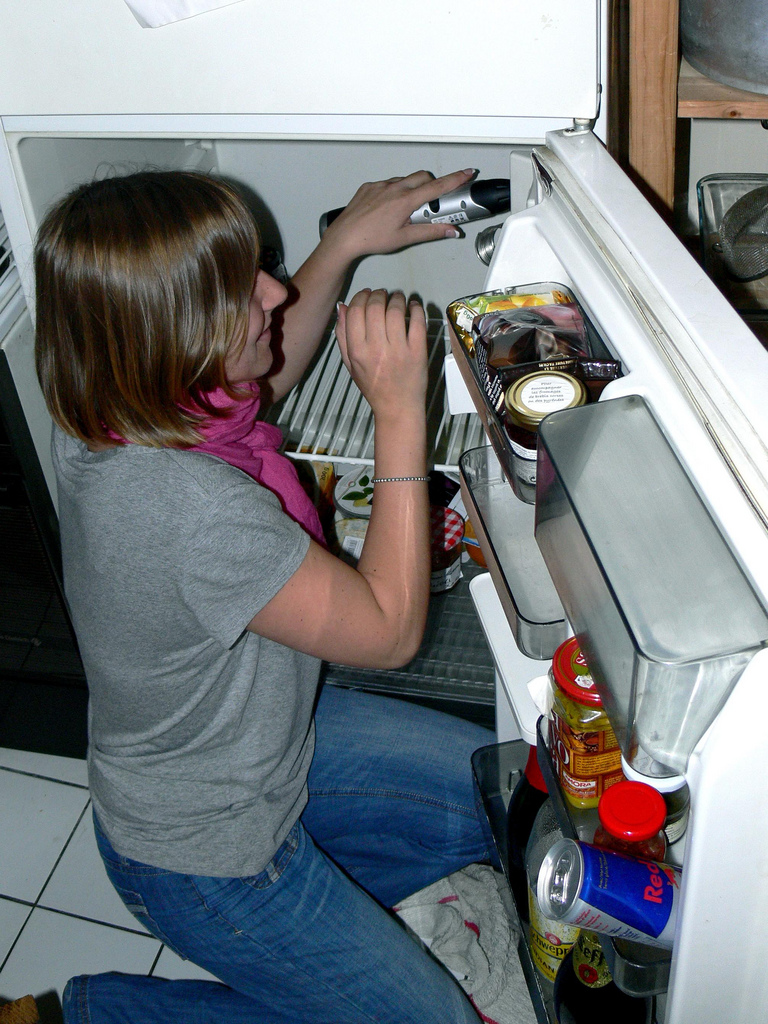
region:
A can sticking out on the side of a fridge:
[564, 863, 652, 909]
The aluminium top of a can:
[552, 850, 571, 905]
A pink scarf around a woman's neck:
[234, 425, 269, 465]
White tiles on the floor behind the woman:
[8, 803, 86, 895]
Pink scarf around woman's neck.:
[169, 395, 316, 526]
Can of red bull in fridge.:
[541, 838, 679, 921]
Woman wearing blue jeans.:
[93, 744, 469, 1021]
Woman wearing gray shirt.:
[36, 470, 316, 874]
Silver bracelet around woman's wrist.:
[366, 462, 431, 493]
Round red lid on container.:
[601, 778, 665, 856]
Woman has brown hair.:
[31, 231, 259, 449]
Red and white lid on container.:
[430, 506, 467, 558]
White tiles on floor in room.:
[6, 777, 146, 987]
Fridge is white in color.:
[12, 32, 740, 906]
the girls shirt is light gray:
[120, 496, 194, 610]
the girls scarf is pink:
[223, 412, 267, 456]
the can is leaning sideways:
[532, 838, 665, 929]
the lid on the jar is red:
[609, 786, 653, 824]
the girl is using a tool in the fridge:
[431, 172, 501, 225]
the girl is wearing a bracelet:
[381, 465, 417, 497]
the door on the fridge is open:
[480, 113, 756, 514]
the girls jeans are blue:
[282, 909, 375, 985]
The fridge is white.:
[576, 249, 704, 356]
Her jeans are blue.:
[243, 917, 351, 986]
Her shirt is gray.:
[98, 688, 207, 786]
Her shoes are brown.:
[2, 956, 60, 1006]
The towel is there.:
[443, 883, 490, 998]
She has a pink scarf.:
[204, 397, 323, 493]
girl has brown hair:
[97, 212, 297, 419]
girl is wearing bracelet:
[364, 464, 415, 496]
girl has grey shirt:
[97, 437, 313, 852]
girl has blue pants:
[160, 752, 536, 1022]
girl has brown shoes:
[6, 980, 56, 1018]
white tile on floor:
[12, 770, 67, 985]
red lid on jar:
[531, 650, 620, 801]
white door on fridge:
[496, 121, 766, 686]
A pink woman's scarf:
[75, 380, 337, 556]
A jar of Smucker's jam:
[410, 493, 469, 600]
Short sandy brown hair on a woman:
[28, 159, 273, 451]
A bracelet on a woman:
[359, 469, 435, 488]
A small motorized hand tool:
[315, 172, 530, 243]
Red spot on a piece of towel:
[456, 908, 487, 943]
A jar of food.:
[584, 791, 650, 854]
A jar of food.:
[627, 737, 687, 834]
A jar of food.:
[534, 631, 648, 781]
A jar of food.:
[496, 368, 604, 472]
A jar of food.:
[430, 498, 483, 589]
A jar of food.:
[327, 458, 389, 564]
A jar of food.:
[284, 448, 337, 508]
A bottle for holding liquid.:
[514, 783, 596, 975]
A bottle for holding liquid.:
[540, 907, 640, 1009]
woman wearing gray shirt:
[9, 173, 547, 1022]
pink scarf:
[98, 373, 330, 545]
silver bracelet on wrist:
[359, 351, 431, 517]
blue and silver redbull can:
[521, 834, 705, 940]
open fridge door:
[457, 147, 762, 1019]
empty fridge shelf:
[99, 206, 499, 473]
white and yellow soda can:
[518, 881, 575, 994]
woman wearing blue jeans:
[47, 649, 615, 1022]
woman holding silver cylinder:
[309, 165, 540, 269]